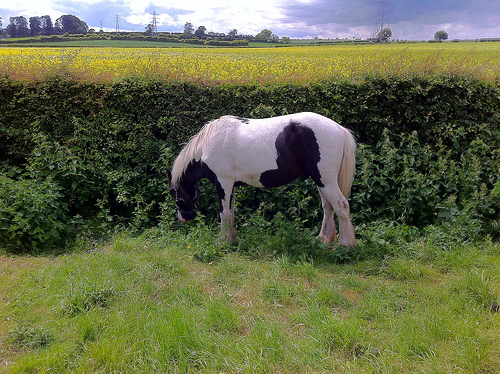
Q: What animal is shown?
A: Horse.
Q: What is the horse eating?
A: Grass.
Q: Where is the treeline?
A: Background.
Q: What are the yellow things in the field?
A: Flowers.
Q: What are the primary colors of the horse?
A: Black and white.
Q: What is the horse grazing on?
A: Grass.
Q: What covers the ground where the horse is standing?
A: Grass.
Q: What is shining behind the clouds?
A: Sun.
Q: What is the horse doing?
A: Grazing in field.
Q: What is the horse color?
A: Black and white.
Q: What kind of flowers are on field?
A: Yellow.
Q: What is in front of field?
A: Weeds.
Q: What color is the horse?
A: Black and white.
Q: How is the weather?
A: Sunny.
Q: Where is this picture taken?
A: A field.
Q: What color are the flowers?
A: Yellow.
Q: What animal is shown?
A: A horse.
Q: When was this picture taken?
A: Daytime.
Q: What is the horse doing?
A: Grazing.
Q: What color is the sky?
A: Blue.